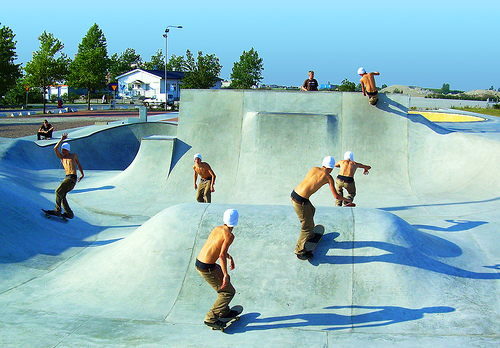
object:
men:
[46, 132, 86, 221]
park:
[8, 11, 493, 338]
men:
[190, 153, 218, 204]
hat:
[343, 151, 354, 162]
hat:
[320, 155, 336, 169]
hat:
[192, 152, 202, 161]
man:
[288, 154, 337, 261]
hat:
[222, 209, 239, 228]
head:
[219, 208, 240, 227]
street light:
[159, 23, 185, 113]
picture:
[3, 5, 498, 342]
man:
[192, 207, 245, 334]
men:
[332, 151, 371, 208]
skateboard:
[202, 304, 244, 331]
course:
[159, 91, 494, 343]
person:
[35, 118, 55, 140]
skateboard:
[295, 224, 326, 261]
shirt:
[37, 124, 54, 133]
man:
[302, 69, 318, 91]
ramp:
[179, 87, 416, 175]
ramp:
[189, 192, 326, 323]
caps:
[61, 142, 72, 152]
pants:
[194, 261, 239, 322]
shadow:
[236, 302, 457, 333]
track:
[68, 91, 408, 286]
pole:
[161, 30, 170, 112]